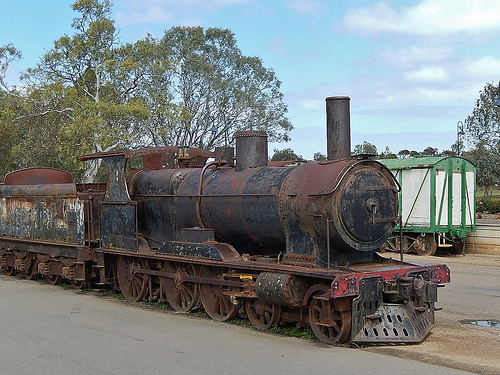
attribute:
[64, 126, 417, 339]
train — old  , black 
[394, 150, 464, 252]
train — green , white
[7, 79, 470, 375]
train — rusted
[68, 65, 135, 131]
tree — tall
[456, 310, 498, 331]
puddle — water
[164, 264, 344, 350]
wheels — on train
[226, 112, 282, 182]
chute —  on top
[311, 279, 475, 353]
grill — metal, on front of train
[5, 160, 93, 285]
car —  of train, rusted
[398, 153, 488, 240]
train car —  green , white 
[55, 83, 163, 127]
trees — tall , green 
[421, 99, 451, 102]
cloud — white 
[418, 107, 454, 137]
sky — blue 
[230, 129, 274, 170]
chute — short, on top of train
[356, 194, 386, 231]
knob — on top of train, lever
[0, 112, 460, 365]
train — Old , rusted , discarded , in a railway junkyard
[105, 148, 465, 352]
engine — old , steam 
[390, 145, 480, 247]
carriage — Green , closed , goods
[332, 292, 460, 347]
guard — for cows, in front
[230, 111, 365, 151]
exhausts — of the engine, for Steam 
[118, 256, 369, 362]
wheels — Steel , now rusted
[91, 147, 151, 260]
cabin — Operater's 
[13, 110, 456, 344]
train — discarded , long , rusted , on road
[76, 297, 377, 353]
grass — growing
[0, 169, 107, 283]
wagon — for Coal storage